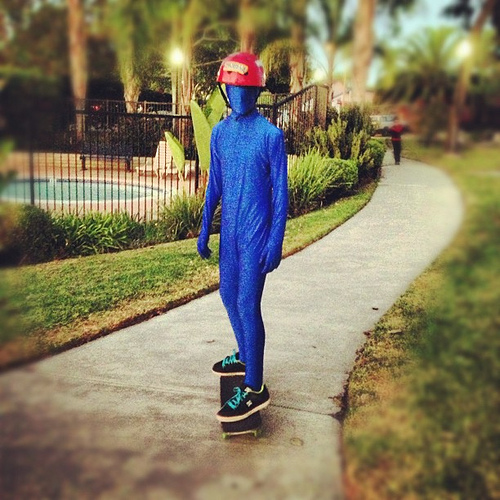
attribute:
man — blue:
[196, 53, 289, 422]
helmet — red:
[217, 51, 267, 90]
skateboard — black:
[219, 377, 263, 441]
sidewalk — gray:
[2, 149, 462, 500]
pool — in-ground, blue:
[2, 179, 167, 205]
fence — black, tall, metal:
[2, 83, 330, 222]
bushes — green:
[2, 104, 378, 267]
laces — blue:
[227, 385, 246, 407]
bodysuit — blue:
[199, 89, 287, 383]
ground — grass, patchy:
[1, 144, 496, 500]